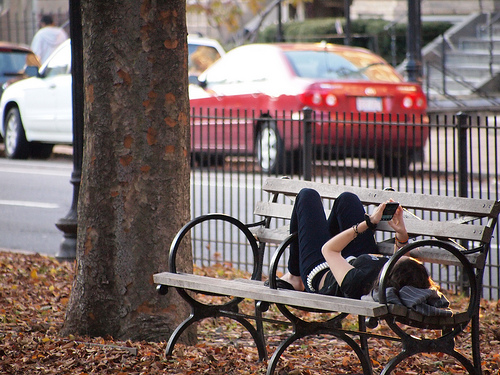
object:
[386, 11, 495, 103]
stairs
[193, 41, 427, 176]
car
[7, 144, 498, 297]
street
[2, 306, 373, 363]
leaves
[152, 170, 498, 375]
bench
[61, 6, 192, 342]
tree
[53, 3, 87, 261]
pole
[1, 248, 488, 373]
ground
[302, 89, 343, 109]
lights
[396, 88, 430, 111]
lights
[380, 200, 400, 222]
cell phone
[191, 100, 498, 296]
fence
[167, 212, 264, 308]
circle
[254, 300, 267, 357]
pole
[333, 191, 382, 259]
pants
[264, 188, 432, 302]
girl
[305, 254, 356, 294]
belt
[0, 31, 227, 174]
cars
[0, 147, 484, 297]
road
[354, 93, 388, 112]
plate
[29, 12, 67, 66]
man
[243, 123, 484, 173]
sidewalk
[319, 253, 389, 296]
shirt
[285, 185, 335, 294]
jeans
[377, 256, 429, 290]
head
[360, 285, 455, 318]
jacket